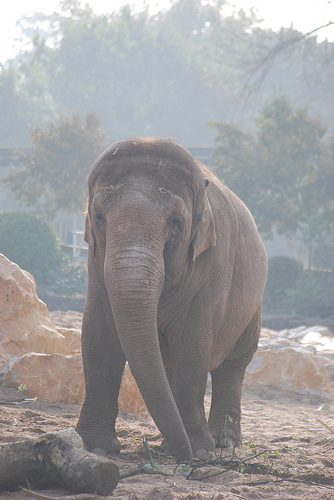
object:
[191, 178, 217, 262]
ear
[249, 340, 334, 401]
rock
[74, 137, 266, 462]
elephant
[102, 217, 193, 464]
trunk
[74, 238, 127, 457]
leg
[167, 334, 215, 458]
leg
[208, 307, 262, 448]
leg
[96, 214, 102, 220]
eye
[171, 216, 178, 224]
eye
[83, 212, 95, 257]
ear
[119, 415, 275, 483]
branches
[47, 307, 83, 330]
rocks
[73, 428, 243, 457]
feet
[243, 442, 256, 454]
leaves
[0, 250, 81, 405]
rocks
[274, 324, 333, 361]
rocks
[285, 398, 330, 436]
sand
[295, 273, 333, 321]
bush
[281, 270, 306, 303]
bush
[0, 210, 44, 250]
bush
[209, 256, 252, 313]
skin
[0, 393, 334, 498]
dirt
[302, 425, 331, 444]
mud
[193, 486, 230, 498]
mud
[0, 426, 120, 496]
log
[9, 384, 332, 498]
ground